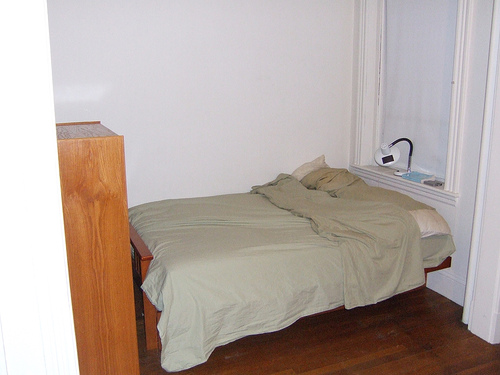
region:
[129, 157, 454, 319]
a double bed is in the room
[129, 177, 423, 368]
a light green blanket is on the bed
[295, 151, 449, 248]
the white pillows have light green cases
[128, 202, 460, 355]
the frame of the bed is wooden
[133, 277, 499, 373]
the room has wooden floors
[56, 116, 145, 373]
a wooden shelf stands at the foot of the bed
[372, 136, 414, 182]
a lamp is at the head of the bed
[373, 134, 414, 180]
the lamp is white with a black gooseneck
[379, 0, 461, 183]
the white shade in the window is down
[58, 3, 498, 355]
the walls of the room are painted flat white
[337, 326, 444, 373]
this is the floor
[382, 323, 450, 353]
the floor is wooden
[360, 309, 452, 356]
the floor is brown in color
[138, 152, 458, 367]
this is a bed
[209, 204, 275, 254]
this is a sheet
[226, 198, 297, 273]
the sheet is grey in color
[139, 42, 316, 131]
this is the wall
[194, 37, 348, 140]
the wall is white in color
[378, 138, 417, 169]
this is a light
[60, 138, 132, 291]
this is a wooden shelf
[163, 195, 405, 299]
this is a bed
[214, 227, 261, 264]
this is a bed cover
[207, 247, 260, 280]
the bed cover is white in color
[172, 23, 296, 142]
this is a wall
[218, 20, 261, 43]
the wall is white in color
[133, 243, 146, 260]
the bed is wooden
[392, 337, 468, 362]
the floor is brown in color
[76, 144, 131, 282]
this is a cupboard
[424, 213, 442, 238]
this is a pillow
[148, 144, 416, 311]
the bed is made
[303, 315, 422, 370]
the floor is brown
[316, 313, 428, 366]
the floor is made of wood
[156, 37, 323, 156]
the wall is white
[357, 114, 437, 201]
the lamp is bent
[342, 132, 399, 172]
the lamp is white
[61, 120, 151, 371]
the shelf is brown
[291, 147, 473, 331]
the pillows are on the bed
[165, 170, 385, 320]
the blanket is gray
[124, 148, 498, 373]
the blanket on the bed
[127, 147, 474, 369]
bed with a green comforter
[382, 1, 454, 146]
white shade on a window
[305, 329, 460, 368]
wooden floor in bedroom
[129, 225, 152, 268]
wooden baseboard of a bed frame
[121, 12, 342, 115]
white wall in a bedroom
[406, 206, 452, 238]
pillow on a bed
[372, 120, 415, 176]
white lamp on window sill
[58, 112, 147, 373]
wooden bureau by a bed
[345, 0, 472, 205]
window in a bedroom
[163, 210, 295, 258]
green comforter on a bed